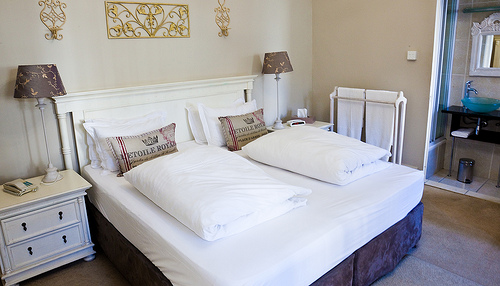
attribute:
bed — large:
[84, 131, 428, 286]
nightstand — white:
[3, 173, 93, 286]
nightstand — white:
[268, 117, 336, 134]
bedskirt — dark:
[311, 208, 421, 286]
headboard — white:
[46, 78, 256, 160]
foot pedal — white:
[465, 179, 469, 183]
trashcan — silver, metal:
[456, 158, 476, 188]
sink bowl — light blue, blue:
[457, 96, 499, 116]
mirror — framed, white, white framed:
[469, 14, 500, 78]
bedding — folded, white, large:
[132, 145, 298, 240]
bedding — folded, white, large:
[245, 127, 391, 187]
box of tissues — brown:
[294, 109, 316, 122]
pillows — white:
[179, 101, 262, 141]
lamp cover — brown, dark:
[13, 63, 68, 104]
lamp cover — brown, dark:
[260, 51, 297, 78]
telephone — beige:
[3, 178, 41, 200]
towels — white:
[338, 81, 394, 144]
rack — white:
[327, 85, 404, 178]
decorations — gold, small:
[36, 1, 238, 45]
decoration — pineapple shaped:
[39, 0, 70, 41]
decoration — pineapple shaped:
[214, 1, 234, 41]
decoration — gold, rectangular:
[106, 1, 192, 42]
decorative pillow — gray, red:
[109, 125, 182, 177]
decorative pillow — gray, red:
[219, 111, 269, 148]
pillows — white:
[89, 118, 158, 176]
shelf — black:
[449, 115, 499, 142]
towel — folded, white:
[447, 124, 476, 143]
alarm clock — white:
[284, 118, 306, 129]